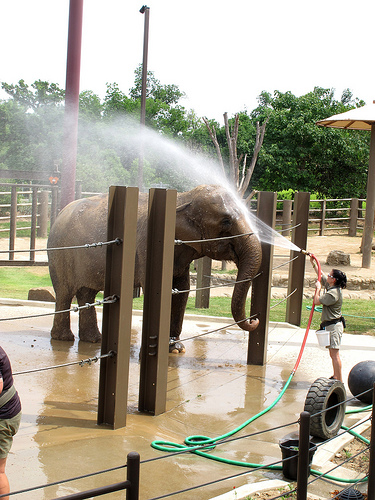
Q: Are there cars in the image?
A: No, there are no cars.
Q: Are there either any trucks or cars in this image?
A: No, there are no cars or trucks.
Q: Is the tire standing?
A: Yes, the tire is standing.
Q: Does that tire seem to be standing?
A: Yes, the tire is standing.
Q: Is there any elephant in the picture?
A: Yes, there is an elephant.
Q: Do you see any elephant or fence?
A: Yes, there is an elephant.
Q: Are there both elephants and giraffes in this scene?
A: No, there is an elephant but no giraffes.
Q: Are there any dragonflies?
A: No, there are no dragonflies.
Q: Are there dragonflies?
A: No, there are no dragonflies.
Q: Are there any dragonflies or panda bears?
A: No, there are no dragonflies or panda bears.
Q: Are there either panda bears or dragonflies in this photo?
A: No, there are no dragonflies or panda bears.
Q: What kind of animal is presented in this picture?
A: The animal is an elephant.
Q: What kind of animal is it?
A: The animal is an elephant.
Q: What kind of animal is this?
A: This is an elephant.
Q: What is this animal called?
A: This is an elephant.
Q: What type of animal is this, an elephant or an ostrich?
A: This is an elephant.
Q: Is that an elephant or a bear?
A: That is an elephant.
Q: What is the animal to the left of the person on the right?
A: The animal is an elephant.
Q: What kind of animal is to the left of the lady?
A: The animal is an elephant.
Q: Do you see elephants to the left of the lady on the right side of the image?
A: Yes, there is an elephant to the left of the lady.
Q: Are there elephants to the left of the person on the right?
A: Yes, there is an elephant to the left of the lady.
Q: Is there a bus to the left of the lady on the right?
A: No, there is an elephant to the left of the lady.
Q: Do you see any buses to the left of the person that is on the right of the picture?
A: No, there is an elephant to the left of the lady.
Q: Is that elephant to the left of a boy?
A: No, the elephant is to the left of the lady.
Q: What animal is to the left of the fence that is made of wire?
A: The animal is an elephant.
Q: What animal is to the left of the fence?
A: The animal is an elephant.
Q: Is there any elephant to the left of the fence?
A: Yes, there is an elephant to the left of the fence.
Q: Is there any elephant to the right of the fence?
A: No, the elephant is to the left of the fence.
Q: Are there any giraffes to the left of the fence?
A: No, there is an elephant to the left of the fence.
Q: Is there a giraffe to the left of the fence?
A: No, there is an elephant to the left of the fence.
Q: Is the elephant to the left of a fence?
A: Yes, the elephant is to the left of a fence.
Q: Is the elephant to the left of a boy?
A: No, the elephant is to the left of a fence.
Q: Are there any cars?
A: No, there are no cars.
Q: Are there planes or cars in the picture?
A: No, there are no cars or planes.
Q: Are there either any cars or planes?
A: No, there are no cars or planes.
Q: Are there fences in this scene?
A: Yes, there is a fence.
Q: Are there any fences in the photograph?
A: Yes, there is a fence.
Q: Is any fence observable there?
A: Yes, there is a fence.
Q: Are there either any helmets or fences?
A: Yes, there is a fence.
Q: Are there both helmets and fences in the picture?
A: No, there is a fence but no helmets.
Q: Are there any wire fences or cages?
A: Yes, there is a wire fence.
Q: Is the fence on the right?
A: Yes, the fence is on the right of the image.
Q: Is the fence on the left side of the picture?
A: No, the fence is on the right of the image.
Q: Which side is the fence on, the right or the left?
A: The fence is on the right of the image.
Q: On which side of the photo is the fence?
A: The fence is on the right of the image.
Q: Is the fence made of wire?
A: Yes, the fence is made of wire.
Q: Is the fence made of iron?
A: No, the fence is made of wire.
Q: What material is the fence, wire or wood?
A: The fence is made of wire.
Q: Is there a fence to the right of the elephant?
A: Yes, there is a fence to the right of the elephant.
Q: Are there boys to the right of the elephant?
A: No, there is a fence to the right of the elephant.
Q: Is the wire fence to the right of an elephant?
A: Yes, the fence is to the right of an elephant.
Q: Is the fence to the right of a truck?
A: No, the fence is to the right of an elephant.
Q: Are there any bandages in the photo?
A: No, there are no bandages.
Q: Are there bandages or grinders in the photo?
A: No, there are no bandages or grinders.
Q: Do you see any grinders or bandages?
A: No, there are no bandages or grinders.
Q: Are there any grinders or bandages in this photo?
A: No, there are no bandages or grinders.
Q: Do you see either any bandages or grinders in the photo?
A: No, there are no bandages or grinders.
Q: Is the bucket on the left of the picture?
A: No, the bucket is on the right of the image.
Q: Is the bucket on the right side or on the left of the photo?
A: The bucket is on the right of the image.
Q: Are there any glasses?
A: No, there are no glasses.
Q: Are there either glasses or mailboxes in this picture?
A: No, there are no glasses or mailboxes.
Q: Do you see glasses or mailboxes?
A: No, there are no glasses or mailboxes.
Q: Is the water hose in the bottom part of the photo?
A: Yes, the water hose is in the bottom of the image.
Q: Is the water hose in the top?
A: No, the water hose is in the bottom of the image.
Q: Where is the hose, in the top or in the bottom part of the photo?
A: The hose is in the bottom of the image.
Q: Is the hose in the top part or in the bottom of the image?
A: The hose is in the bottom of the image.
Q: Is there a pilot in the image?
A: No, there are no pilots.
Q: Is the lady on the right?
A: Yes, the lady is on the right of the image.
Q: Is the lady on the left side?
A: No, the lady is on the right of the image.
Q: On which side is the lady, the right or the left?
A: The lady is on the right of the image.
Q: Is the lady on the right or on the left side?
A: The lady is on the right of the image.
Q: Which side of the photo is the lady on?
A: The lady is on the right of the image.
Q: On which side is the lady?
A: The lady is on the right of the image.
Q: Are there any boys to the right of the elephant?
A: No, there is a lady to the right of the elephant.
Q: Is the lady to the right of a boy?
A: No, the lady is to the right of the elephant.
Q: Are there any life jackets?
A: No, there are no life jackets.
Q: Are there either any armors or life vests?
A: No, there are no life vests or armors.